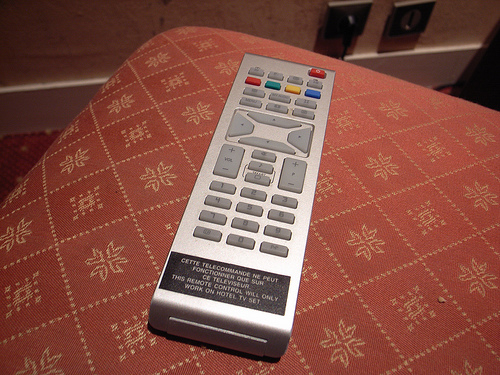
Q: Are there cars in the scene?
A: No, there are no cars.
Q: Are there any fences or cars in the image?
A: No, there are no cars or fences.